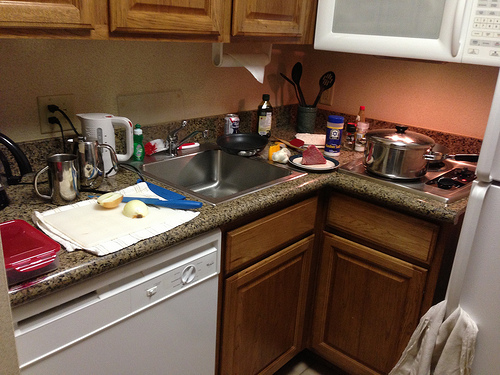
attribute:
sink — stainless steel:
[140, 141, 305, 209]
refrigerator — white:
[451, 102, 498, 359]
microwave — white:
[299, 0, 494, 100]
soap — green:
[116, 110, 156, 171]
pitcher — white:
[72, 106, 136, 146]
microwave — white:
[301, 10, 483, 71]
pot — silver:
[360, 120, 442, 184]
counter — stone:
[12, 166, 220, 234]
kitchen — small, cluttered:
[1, 2, 498, 353]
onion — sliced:
[93, 180, 157, 227]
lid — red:
[3, 212, 75, 282]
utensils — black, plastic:
[278, 71, 300, 107]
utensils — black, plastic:
[289, 61, 306, 103]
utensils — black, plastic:
[311, 69, 333, 106]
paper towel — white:
[212, 45, 281, 81]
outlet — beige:
[38, 93, 78, 133]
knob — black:
[391, 120, 411, 135]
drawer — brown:
[325, 194, 444, 265]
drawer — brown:
[221, 190, 322, 270]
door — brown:
[308, 229, 426, 374]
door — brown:
[225, 226, 316, 374]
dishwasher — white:
[0, 227, 226, 374]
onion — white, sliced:
[94, 189, 150, 219]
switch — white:
[145, 283, 161, 298]